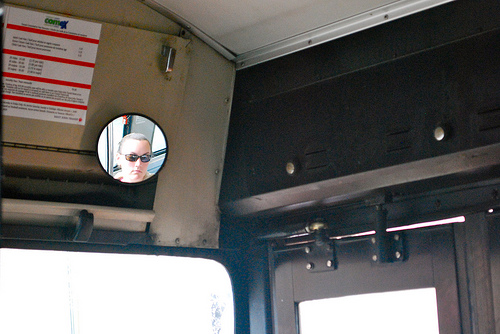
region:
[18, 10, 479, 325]
photo from inside a vehicle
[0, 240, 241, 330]
front window of the bus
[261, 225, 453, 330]
one of the door panels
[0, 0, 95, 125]
informational card for the vehicle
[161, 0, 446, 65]
rounded ceiling of the bus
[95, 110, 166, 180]
reflection of a person sitting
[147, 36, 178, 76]
handle to a metal cabinet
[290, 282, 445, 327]
door panel's window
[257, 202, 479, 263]
metal door mechanism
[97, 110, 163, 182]
mirror for bus driver to look back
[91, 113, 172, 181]
circle mirror on front of bus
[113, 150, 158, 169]
black sunglasses on face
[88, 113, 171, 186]
woman's face in mirror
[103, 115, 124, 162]
window on side of bus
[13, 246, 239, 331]
front window on bus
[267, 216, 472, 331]
side door on bus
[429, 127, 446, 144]
silver screws on side of bus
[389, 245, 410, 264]
silver screws on door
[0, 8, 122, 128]
white and red sign on bus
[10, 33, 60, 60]
black writing on the sign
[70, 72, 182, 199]
a round mirror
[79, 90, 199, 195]
a round mirror with a black border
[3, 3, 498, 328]
the interior of a bus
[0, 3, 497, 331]
the inside of a bus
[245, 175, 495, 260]
the hydraulic hinge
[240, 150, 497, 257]
the bus door hinge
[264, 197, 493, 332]
this is the bus door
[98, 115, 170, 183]
reflection of a passenger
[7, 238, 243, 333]
the top of the windshield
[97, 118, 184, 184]
The woman's face is seen in the mirror.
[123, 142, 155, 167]
The woman is wearing sunglasses.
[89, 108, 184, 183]
The mirror is round.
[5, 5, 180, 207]
The mirror is on the visor of the bus.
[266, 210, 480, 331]
The bus door is closed.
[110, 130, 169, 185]
The lady is not talking.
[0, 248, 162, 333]
Light is coming through the window.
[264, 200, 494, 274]
The metal rod is over the bus door.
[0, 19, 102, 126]
The letter has four red lines.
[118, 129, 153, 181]
Woman's reflection in mirror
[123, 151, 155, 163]
Woman wearing sunglasses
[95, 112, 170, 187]
Round mirror on wall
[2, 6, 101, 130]
Red and white sign on wall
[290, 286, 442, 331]
Window in the door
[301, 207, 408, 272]
Bolts on objects hold door shut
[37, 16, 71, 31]
Small emblem on sign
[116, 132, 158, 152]
Woman's hair is tied back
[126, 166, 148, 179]
Woman is frowning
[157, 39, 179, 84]
Latch to a compartment